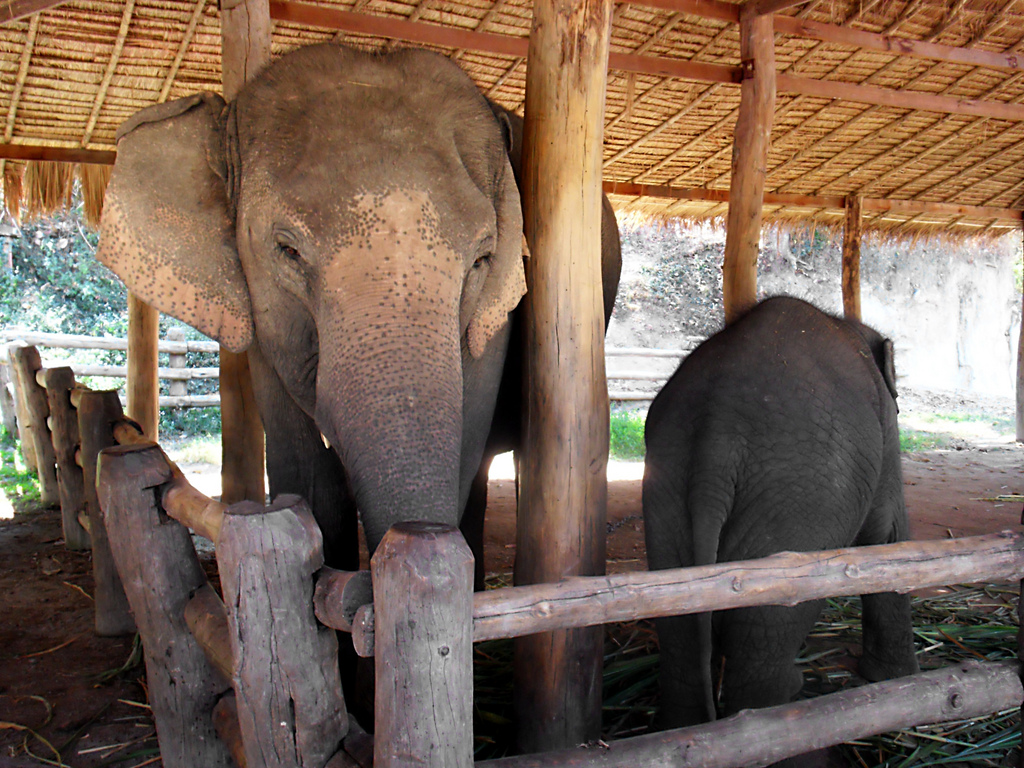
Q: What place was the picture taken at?
A: It was taken at the pen.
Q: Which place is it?
A: It is a pen.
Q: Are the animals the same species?
A: Yes, all the animals are elephants.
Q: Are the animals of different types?
A: No, all the animals are elephants.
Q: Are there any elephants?
A: Yes, there is an elephant.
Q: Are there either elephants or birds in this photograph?
A: Yes, there is an elephant.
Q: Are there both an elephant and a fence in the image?
A: Yes, there are both an elephant and a fence.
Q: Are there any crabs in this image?
A: No, there are no crabs.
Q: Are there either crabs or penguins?
A: No, there are no crabs or penguins.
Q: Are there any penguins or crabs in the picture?
A: No, there are no crabs or penguins.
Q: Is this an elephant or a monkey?
A: This is an elephant.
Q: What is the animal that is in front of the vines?
A: The animal is an elephant.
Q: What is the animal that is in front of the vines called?
A: The animal is an elephant.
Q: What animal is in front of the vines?
A: The animal is an elephant.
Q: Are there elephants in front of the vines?
A: Yes, there is an elephant in front of the vines.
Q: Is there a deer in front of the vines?
A: No, there is an elephant in front of the vines.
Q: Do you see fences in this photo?
A: Yes, there is a fence.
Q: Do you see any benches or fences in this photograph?
A: Yes, there is a fence.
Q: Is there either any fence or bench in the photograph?
A: Yes, there is a fence.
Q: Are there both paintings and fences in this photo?
A: No, there is a fence but no paintings.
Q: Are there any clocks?
A: No, there are no clocks.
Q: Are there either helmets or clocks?
A: No, there are no clocks or helmets.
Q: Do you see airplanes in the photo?
A: No, there are no airplanes.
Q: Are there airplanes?
A: No, there are no airplanes.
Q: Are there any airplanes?
A: No, there are no airplanes.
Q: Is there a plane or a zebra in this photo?
A: No, there are no airplanes or zebras.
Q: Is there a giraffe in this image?
A: No, there are no giraffes.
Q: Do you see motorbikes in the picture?
A: No, there are no motorbikes.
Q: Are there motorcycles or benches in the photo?
A: No, there are no motorcycles or benches.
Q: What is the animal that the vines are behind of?
A: The animal is an elephant.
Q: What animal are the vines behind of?
A: The vines are behind the elephant.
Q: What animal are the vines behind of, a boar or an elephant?
A: The vines are behind an elephant.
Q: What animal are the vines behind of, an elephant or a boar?
A: The vines are behind an elephant.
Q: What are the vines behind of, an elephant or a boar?
A: The vines are behind an elephant.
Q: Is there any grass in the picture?
A: Yes, there is grass.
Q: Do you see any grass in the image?
A: Yes, there is grass.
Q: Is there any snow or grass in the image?
A: Yes, there is grass.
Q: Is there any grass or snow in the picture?
A: Yes, there is grass.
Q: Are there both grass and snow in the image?
A: No, there is grass but no snow.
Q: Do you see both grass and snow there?
A: No, there is grass but no snow.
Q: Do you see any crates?
A: No, there are no crates.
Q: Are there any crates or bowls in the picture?
A: No, there are no crates or bowls.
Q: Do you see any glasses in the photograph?
A: No, there are no glasses.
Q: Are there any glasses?
A: No, there are no glasses.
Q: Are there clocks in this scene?
A: No, there are no clocks.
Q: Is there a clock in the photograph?
A: No, there are no clocks.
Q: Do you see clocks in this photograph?
A: No, there are no clocks.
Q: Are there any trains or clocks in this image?
A: No, there are no clocks or trains.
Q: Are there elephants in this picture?
A: Yes, there is an elephant.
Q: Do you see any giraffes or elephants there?
A: Yes, there is an elephant.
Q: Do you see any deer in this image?
A: No, there are no deer.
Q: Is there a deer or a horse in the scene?
A: No, there are no deer or horses.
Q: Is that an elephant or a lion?
A: That is an elephant.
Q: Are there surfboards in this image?
A: No, there are no surfboards.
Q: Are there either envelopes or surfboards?
A: No, there are no surfboards or envelopes.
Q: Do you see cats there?
A: No, there are no cats.